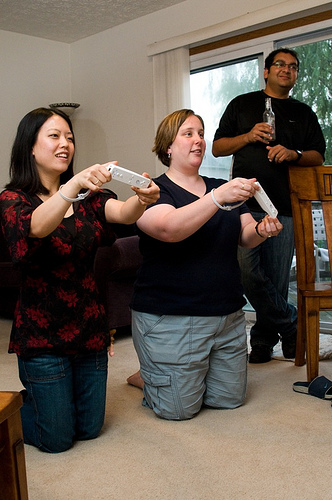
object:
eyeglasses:
[264, 58, 299, 72]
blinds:
[153, 46, 191, 178]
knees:
[146, 382, 203, 422]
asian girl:
[0, 106, 161, 454]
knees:
[72, 410, 104, 442]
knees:
[34, 406, 76, 454]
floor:
[0, 309, 332, 499]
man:
[211, 47, 326, 365]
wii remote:
[57, 161, 152, 203]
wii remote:
[211, 181, 280, 220]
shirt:
[0, 180, 118, 362]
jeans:
[16, 354, 107, 456]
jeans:
[236, 207, 299, 352]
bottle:
[262, 97, 277, 142]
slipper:
[291, 375, 332, 402]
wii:
[58, 161, 279, 221]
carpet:
[0, 319, 332, 500]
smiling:
[180, 126, 206, 157]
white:
[252, 181, 277, 219]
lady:
[123, 107, 284, 422]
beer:
[262, 97, 277, 142]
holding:
[255, 121, 279, 147]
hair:
[0, 107, 76, 197]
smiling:
[46, 126, 75, 165]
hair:
[151, 109, 205, 168]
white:
[155, 153, 170, 177]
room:
[0, 0, 332, 499]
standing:
[211, 46, 326, 364]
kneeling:
[17, 347, 108, 454]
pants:
[130, 310, 248, 422]